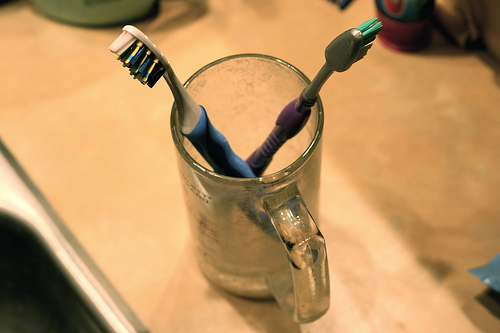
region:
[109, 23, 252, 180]
a white and blue toothbrush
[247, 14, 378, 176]
a purple and copper colored toothbrush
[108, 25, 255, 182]
a toothbrush with blue, yellow, and white bristles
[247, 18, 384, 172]
a toothbrush with blue bristles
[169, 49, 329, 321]
a clear glass mug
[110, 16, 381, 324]
a clear glass mug with two toothbrushes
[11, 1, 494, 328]
a brown wooden table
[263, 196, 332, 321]
a glass handle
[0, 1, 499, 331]
wood topped table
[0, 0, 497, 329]
a very blurry background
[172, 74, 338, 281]
glass mug with toothbrushes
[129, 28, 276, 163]
tooth brush in glass mug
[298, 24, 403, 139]
tooth brush in glass mug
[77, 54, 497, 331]
tan counter under glass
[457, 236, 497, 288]
corner of blue paper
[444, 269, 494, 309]
shadow of blue paper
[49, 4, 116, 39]
green object on upper left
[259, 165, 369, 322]
glass handle of mug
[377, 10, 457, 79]
bottom of red bottle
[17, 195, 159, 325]
white edge of counter on left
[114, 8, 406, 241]
two toothbrushes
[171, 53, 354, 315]
glass cup with handle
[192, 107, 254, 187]
blue handle of toothbrush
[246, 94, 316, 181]
purple handle of toothbrush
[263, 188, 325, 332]
handle of glass mug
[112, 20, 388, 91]
bristles of two toothbrushes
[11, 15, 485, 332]
counter mug of toothbrushes is on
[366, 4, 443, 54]
tube of toothpaste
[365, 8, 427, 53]
red cap of toothpaste tube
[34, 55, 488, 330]
square of light on countertop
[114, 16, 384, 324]
two tooth brushes in a cup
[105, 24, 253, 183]
a blue toothbrush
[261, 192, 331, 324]
handle on a glass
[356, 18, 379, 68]
the green bristles of a toothbrush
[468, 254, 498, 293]
tip of blue paper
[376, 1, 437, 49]
top of toothpaste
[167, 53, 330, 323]
a glass mug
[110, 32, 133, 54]
white section of bristles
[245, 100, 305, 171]
a rubber purple handle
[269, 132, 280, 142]
purple stripe on toothbrush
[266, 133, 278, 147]
purple stripe on toothbrush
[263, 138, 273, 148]
purple stripe on toothbrush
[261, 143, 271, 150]
purple stripe on toothbrush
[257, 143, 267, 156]
purple stripe on toothbrush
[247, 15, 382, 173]
purple colored tooth brush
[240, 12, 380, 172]
tooth brush in glass cup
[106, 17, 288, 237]
blue colored toothbrush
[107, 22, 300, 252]
toothbrush in glass cup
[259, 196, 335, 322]
glass handle on cup